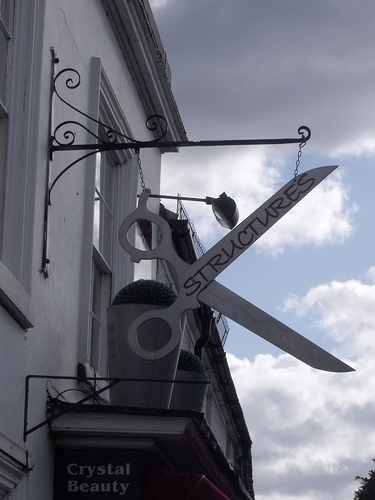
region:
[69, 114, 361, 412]
a scissor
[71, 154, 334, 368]
white scissor shaped sign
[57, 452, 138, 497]
the words Crystal Beauty in white type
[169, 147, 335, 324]
STRUCTURES written in black font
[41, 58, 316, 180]
black pole holding sign from chains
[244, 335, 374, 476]
fluffy white clouds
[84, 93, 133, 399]
tall rectangular glass window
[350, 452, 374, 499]
edge of a tree with leaves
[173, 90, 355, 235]
white clouds in blue sky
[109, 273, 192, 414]
plant in pot on top of door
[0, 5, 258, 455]
white stucco building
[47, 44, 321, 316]
A black metal sign hanger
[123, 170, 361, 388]
Silver scissors hanging from iron hanger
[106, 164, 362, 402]
Scissors with blades open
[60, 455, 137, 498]
Crystal Beauty in white letters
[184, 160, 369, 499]
White fluffy clouds in sky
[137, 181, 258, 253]
Light coming out from building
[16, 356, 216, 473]
Plain metal sign holder without sign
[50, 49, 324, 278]
Fancy black sign holder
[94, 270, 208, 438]
Two cups of slushies on ledge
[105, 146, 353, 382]
Scissors have Structures on blade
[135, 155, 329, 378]
a scissor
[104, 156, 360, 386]
Scissors haning from metal bar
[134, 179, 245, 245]
A light coming out from building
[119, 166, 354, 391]
Scissors with the word Structures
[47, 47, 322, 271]
Black iron bar holding sign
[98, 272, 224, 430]
Two big slushies on top of awning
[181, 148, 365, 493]
White clouds in the sky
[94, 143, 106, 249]
Reflection of clouds in window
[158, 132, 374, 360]
Blue sky poking out from clouds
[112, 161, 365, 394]
Silver scissors with word on them